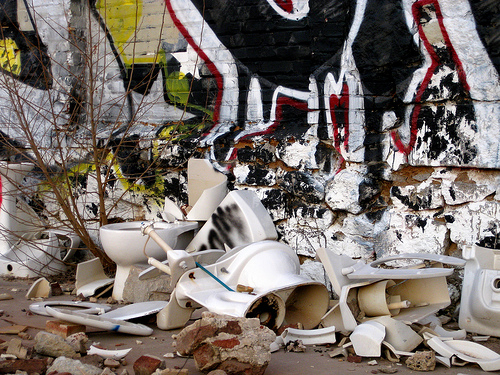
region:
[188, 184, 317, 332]
a broken toilet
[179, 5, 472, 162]
graffiti on a wall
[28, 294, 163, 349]
broken toilet seat lids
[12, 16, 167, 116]
more graffiti on the wall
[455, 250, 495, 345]
a broken sink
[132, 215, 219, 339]
broken bathroom fixtures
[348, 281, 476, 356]
the inside of a broken toilet tank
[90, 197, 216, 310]
more broken toilets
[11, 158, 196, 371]
the broken toilets are white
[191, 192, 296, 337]
this broken toilet has grafitti on it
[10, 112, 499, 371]
a lot of broken toilets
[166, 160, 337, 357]
broken toilet with Mom spray painted on it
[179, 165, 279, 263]
black spray painted "mom"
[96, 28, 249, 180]
spray painted star on a brick wall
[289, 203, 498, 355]
broken toilet chunks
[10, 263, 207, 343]
toilet seat and lid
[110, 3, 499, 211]
spray painted walls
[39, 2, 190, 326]
small dead tree near broken toilets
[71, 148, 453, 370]
broken toilets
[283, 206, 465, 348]
toilet seat on top of a chunk of broken toilet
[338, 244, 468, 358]
a broken toilet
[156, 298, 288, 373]
a big rock on the ground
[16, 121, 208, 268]
a leafless tree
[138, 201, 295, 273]
graffiti on the broken toilet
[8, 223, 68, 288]
a urinal on the ground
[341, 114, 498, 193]
black graffiti on a white wall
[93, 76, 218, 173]
a white star trimmed in yellow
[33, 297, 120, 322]
a toilet seat on the ground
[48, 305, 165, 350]
a toilet lid with blue paint on it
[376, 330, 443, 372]
a small rock on the ground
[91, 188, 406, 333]
white broken toilets on ground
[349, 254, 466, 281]
upside down toilet seat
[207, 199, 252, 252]
spray paint on toilet tank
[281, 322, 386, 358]
pieces of broken toilet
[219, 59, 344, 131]
spray paint on brick wall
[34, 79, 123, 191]
tree with no leaves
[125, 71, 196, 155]
white star on wall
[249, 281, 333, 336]
bottom of tipped toilet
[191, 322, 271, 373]
brick and cement on ground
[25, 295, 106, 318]
toilet seat on ground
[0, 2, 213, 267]
a tree that is growing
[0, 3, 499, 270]
some painting on a wall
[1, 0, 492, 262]
an old wall with some painting on it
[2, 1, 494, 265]
a painting with white paint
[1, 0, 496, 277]
a painting with black paint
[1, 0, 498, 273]
a painting with red paint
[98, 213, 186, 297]
a white toilet seat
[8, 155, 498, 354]
broken toilet seats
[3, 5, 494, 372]
it is a daytime scene